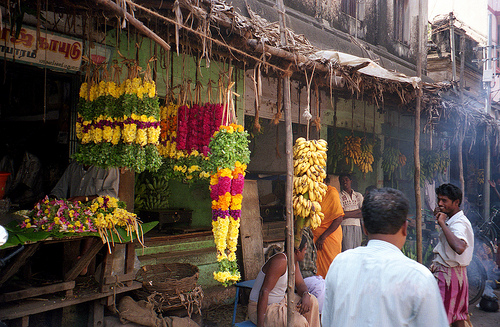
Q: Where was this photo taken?
A: Market.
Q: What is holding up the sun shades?
A: Sticks.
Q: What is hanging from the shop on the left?
A: Flowers.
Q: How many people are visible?
A: Seven.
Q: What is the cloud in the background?
A: Smoke.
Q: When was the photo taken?
A: Daytime.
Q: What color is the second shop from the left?
A: Green.